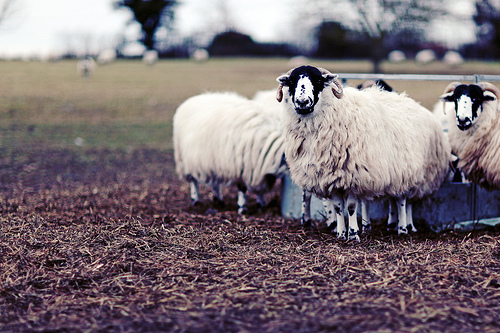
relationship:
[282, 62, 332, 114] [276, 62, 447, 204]
face on sheep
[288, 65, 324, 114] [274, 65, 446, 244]
face on sheep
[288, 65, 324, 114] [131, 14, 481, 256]
face on sheep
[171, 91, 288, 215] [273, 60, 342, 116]
sheep has face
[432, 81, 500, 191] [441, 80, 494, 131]
sheep has face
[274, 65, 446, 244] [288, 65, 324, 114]
sheep has face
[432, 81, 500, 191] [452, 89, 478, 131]
sheep has face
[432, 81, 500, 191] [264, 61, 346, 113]
sheep has face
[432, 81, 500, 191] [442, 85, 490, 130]
sheep has face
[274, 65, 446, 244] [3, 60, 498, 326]
sheep in field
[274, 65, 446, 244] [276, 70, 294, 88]
sheep has ears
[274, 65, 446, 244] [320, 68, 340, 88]
sheep has ears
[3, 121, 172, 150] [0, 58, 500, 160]
grass in field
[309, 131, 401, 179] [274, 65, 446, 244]
long fur on sheep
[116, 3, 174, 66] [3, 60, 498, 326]
tall tree in field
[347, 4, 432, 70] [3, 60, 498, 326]
tall tree in field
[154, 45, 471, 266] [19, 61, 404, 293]
sheep in field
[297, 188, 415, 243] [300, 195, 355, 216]
legs have spots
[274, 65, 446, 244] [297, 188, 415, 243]
sheep has legs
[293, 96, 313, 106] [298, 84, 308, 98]
nose has spots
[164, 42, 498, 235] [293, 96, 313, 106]
sheep has nose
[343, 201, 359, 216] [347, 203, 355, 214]
knee has black spot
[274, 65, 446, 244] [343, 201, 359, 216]
sheep has knee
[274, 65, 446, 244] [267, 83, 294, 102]
sheep has horn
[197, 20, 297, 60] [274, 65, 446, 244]
building behind sheep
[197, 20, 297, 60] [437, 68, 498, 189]
building behind sheep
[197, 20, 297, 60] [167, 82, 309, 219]
building behind sheep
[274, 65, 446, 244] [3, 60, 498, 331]
sheep in yard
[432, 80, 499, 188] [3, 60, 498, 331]
sheep in yard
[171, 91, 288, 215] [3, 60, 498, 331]
sheep in yard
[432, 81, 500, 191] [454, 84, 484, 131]
sheep has face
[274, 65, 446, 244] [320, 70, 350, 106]
sheep has horn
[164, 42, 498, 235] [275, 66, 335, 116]
sheep has face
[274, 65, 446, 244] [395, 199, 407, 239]
sheep has leg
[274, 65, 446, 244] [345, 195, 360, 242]
sheep has leg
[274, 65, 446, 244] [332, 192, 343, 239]
sheep has leg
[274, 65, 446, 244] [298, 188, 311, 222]
sheep has leg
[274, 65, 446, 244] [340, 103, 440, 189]
sheep has white wool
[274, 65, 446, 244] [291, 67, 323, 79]
sheep has black wool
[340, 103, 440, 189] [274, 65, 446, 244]
white wool on sheep